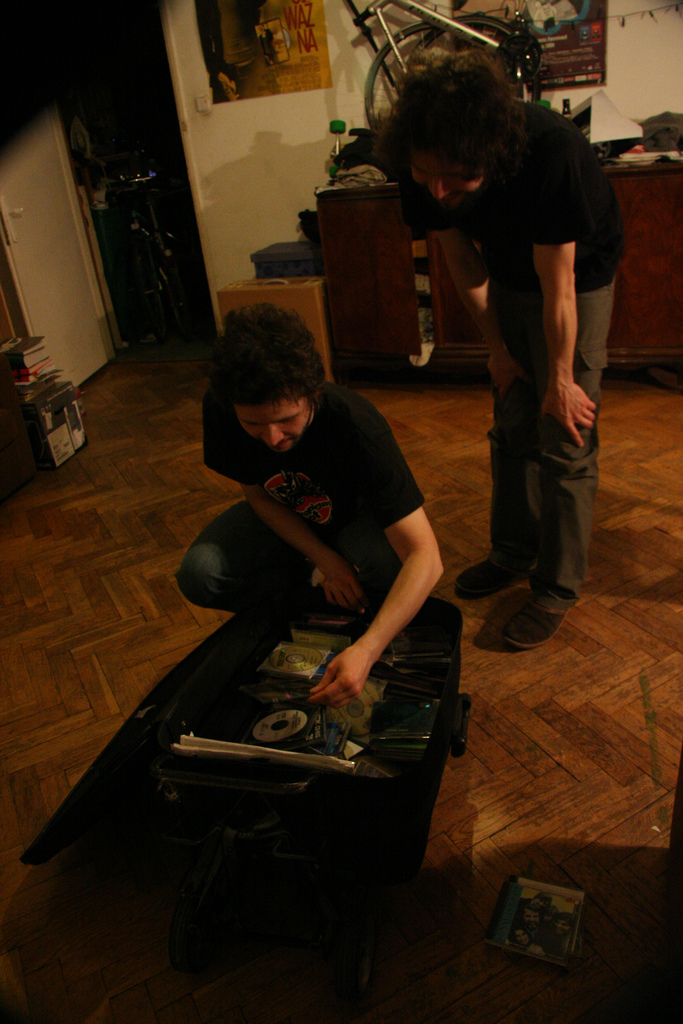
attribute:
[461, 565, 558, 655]
shoe — brown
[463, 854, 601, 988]
cd — music